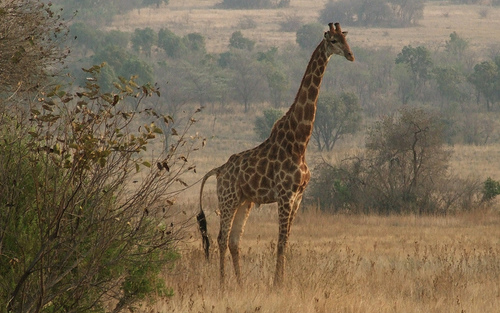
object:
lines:
[216, 151, 311, 209]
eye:
[330, 39, 338, 43]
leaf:
[121, 112, 132, 121]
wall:
[433, 125, 475, 183]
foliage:
[10, 0, 210, 311]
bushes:
[0, 0, 79, 96]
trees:
[136, 25, 274, 111]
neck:
[271, 52, 332, 150]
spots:
[230, 158, 288, 193]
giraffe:
[196, 21, 355, 292]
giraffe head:
[323, 22, 355, 62]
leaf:
[163, 161, 170, 172]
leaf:
[141, 159, 152, 168]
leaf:
[166, 199, 176, 206]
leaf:
[111, 94, 120, 107]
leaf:
[194, 104, 206, 112]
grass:
[187, 246, 352, 311]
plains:
[308, 217, 469, 301]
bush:
[1, 64, 208, 313]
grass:
[340, 191, 463, 276]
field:
[0, 0, 499, 313]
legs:
[275, 195, 303, 280]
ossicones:
[327, 21, 341, 32]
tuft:
[195, 210, 212, 263]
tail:
[195, 167, 218, 259]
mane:
[289, 38, 323, 119]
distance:
[0, 0, 500, 121]